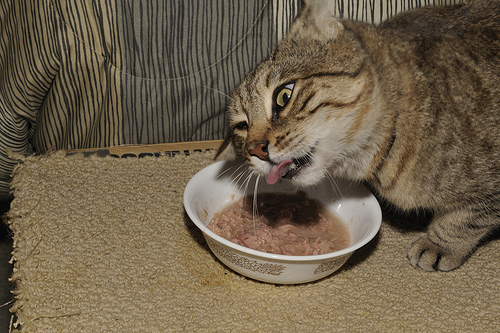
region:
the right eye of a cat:
[262, 74, 319, 128]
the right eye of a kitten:
[267, 71, 307, 128]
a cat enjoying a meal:
[122, 2, 498, 297]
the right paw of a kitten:
[400, 187, 499, 299]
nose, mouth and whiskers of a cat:
[216, 136, 363, 228]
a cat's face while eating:
[192, 2, 434, 205]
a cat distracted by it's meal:
[152, 2, 499, 298]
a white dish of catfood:
[172, 145, 409, 312]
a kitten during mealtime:
[142, 2, 497, 305]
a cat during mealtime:
[137, 2, 496, 329]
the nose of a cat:
[242, 136, 277, 167]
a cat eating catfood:
[171, 2, 498, 294]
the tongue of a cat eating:
[261, 145, 320, 198]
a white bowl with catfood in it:
[176, 148, 391, 307]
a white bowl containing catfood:
[164, 137, 389, 299]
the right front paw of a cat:
[398, 192, 491, 309]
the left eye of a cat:
[262, 72, 308, 122]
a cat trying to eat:
[167, 1, 496, 296]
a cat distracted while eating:
[173, 2, 493, 287]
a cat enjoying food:
[155, 4, 497, 311]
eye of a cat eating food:
[268, 77, 303, 125]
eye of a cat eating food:
[235, 115, 250, 133]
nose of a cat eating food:
[247, 135, 274, 164]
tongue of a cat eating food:
[262, 155, 297, 188]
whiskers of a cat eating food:
[204, 152, 266, 247]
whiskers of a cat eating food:
[303, 138, 369, 203]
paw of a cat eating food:
[401, 206, 483, 278]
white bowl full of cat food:
[172, 150, 392, 297]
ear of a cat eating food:
[278, 1, 343, 43]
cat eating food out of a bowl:
[182, 0, 498, 285]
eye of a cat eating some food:
[268, 76, 305, 116]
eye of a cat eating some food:
[232, 113, 253, 136]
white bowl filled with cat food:
[174, 149, 386, 288]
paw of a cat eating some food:
[403, 224, 465, 275]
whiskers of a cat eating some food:
[200, 153, 272, 245]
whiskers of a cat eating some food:
[292, 133, 381, 203]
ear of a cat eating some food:
[284, 0, 348, 40]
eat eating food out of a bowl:
[157, 3, 497, 288]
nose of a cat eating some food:
[245, 134, 272, 161]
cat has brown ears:
[218, 25, 329, 157]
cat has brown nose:
[216, 142, 284, 179]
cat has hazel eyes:
[230, 67, 294, 139]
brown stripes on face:
[313, 53, 373, 138]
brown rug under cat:
[39, 169, 155, 323]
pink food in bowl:
[214, 191, 346, 289]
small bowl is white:
[153, 166, 355, 283]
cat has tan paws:
[413, 209, 483, 275]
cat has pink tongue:
[257, 144, 304, 185]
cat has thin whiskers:
[218, 146, 373, 228]